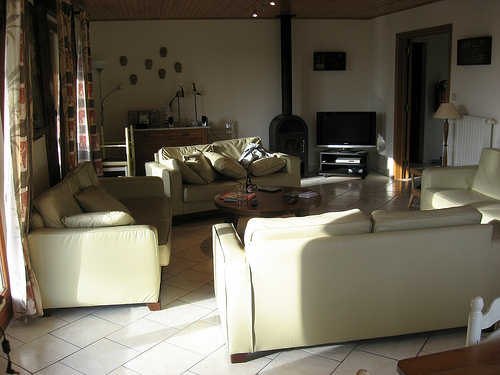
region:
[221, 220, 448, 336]
cream color couch in the floor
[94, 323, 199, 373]
whitecolor tiles in the floor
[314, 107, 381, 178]
TV with stand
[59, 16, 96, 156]
multi-color curtains hanging in the window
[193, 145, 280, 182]
pillow kept in the couch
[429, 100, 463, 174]
night lamp kept near the couch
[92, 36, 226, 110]
lamp with decorated wall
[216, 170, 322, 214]
somethings kept some Wooden Teapoy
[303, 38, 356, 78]
photo frames in the wall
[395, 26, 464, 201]
door with lamp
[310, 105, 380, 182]
LCD television on a stand in corner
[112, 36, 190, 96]
group of six decorative wall items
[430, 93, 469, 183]
floor lamp stand with beige colored shade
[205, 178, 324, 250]
round coffee table in center of room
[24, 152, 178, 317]
cream colored leather look sofa with pillows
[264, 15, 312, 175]
freestanding fireplace near white wall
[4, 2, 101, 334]
decorative curtains hanging in room windows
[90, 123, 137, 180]
two chairs with one stacked on the other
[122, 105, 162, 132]
stereo system on light wood cabinet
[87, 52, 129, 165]
floor lamp with extended lamp and two frosted white shades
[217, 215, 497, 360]
white sofa in room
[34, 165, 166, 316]
white sofa in room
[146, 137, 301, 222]
white sofa in room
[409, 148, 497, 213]
white sofa in room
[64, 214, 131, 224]
white cushion on sofa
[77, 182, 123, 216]
white cushion on sofa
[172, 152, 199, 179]
white cushion on sofa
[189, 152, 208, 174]
white cushion on sofa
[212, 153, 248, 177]
white cushion on sofa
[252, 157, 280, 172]
white cushion on sofa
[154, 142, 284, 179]
Messy pillows on a sofa.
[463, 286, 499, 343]
A piece of the back of a white chair.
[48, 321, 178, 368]
White, polished tile on the floor.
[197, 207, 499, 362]
The back of a beige sofa.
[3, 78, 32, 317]
A multicolored curtain.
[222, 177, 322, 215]
A small coffee table.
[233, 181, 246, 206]
An empty glass on the coffee table.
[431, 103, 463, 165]
A lamp in the corner.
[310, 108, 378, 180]
A flat screen TV and entertainment center.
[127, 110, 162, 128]
A small personal stereo.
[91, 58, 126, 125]
A two headed lamp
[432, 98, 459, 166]
A standing lamp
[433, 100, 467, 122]
A white lamp shade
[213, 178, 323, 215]
A round table in between couches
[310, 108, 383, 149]
A tv in the corner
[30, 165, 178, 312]
A cream colored sofa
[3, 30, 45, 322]
Flower patterned curtains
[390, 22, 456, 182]
Wood around the edge of a doorway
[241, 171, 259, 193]
A bottle on the table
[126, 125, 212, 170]
A wooden dresser